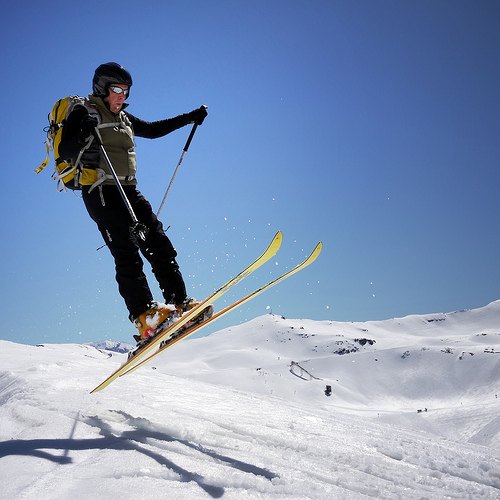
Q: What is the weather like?
A: It is clear.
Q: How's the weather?
A: It is clear.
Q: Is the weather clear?
A: Yes, it is clear.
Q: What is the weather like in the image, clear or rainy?
A: It is clear.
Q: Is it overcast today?
A: No, it is clear.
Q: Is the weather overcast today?
A: No, it is clear.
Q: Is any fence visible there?
A: No, there are no fences.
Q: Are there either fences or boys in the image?
A: No, there are no fences or boys.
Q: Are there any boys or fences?
A: No, there are no fences or boys.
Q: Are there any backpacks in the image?
A: Yes, there is a backpack.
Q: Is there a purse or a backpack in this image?
A: Yes, there is a backpack.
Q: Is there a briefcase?
A: No, there are no briefcases.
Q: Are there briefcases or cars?
A: No, there are no briefcases or cars.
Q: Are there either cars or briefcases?
A: No, there are no briefcases or cars.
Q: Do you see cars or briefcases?
A: No, there are no briefcases or cars.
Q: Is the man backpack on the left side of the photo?
A: Yes, the backpack is on the left of the image.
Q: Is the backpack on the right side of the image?
A: No, the backpack is on the left of the image.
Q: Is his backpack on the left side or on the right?
A: The backpack is on the left of the image.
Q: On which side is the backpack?
A: The backpack is on the left of the image.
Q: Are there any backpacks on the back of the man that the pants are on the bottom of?
A: Yes, there is a backpack on the back of the man.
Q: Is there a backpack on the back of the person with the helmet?
A: Yes, there is a backpack on the back of the man.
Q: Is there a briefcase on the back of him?
A: No, there is a backpack on the back of the man.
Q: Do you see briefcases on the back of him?
A: No, there is a backpack on the back of the man.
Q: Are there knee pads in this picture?
A: No, there are no knee pads.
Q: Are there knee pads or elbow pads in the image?
A: No, there are no knee pads or elbow pads.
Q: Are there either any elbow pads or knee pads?
A: No, there are no knee pads or elbow pads.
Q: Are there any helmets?
A: Yes, there is a helmet.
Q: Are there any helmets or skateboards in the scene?
A: Yes, there is a helmet.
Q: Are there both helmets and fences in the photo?
A: No, there is a helmet but no fences.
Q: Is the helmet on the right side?
A: No, the helmet is on the left of the image.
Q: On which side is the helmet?
A: The helmet is on the left of the image.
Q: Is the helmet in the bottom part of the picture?
A: No, the helmet is in the top of the image.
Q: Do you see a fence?
A: No, there are no fences.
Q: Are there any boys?
A: No, there are no boys.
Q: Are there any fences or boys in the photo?
A: No, there are no boys or fences.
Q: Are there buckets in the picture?
A: No, there are no buckets.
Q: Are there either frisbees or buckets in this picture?
A: No, there are no buckets or frisbees.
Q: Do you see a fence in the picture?
A: No, there are no fences.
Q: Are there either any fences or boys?
A: No, there are no boys or fences.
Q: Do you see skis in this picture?
A: Yes, there are skis.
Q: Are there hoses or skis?
A: Yes, there are skis.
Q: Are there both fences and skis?
A: No, there are skis but no fences.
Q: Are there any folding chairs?
A: No, there are no folding chairs.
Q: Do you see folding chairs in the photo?
A: No, there are no folding chairs.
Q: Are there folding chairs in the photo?
A: No, there are no folding chairs.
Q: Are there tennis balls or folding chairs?
A: No, there are no folding chairs or tennis balls.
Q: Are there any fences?
A: No, there are no fences.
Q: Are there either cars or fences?
A: No, there are no fences or cars.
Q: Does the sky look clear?
A: Yes, the sky is clear.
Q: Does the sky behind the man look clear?
A: Yes, the sky is clear.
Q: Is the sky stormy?
A: No, the sky is clear.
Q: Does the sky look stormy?
A: No, the sky is clear.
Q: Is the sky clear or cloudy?
A: The sky is clear.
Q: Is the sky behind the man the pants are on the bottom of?
A: Yes, the sky is behind the man.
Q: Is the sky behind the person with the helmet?
A: Yes, the sky is behind the man.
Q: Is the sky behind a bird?
A: No, the sky is behind the man.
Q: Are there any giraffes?
A: No, there are no giraffes.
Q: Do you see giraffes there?
A: No, there are no giraffes.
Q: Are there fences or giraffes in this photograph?
A: No, there are no giraffes or fences.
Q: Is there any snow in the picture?
A: Yes, there is snow.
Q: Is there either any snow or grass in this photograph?
A: Yes, there is snow.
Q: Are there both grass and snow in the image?
A: No, there is snow but no grass.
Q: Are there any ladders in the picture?
A: No, there are no ladders.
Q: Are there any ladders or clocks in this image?
A: No, there are no ladders or clocks.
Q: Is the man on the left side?
A: Yes, the man is on the left of the image.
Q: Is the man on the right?
A: No, the man is on the left of the image.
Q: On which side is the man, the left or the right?
A: The man is on the left of the image.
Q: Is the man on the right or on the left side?
A: The man is on the left of the image.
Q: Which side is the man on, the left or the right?
A: The man is on the left of the image.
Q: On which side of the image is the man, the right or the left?
A: The man is on the left of the image.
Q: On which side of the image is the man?
A: The man is on the left of the image.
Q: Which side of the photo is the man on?
A: The man is on the left of the image.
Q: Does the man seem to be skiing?
A: Yes, the man is skiing.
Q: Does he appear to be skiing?
A: Yes, the man is skiing.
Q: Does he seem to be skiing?
A: Yes, the man is skiing.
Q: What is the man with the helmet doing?
A: The man is skiing.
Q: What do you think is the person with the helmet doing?
A: The man is skiing.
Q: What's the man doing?
A: The man is skiing.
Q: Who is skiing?
A: The man is skiing.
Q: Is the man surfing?
A: No, the man is skiing.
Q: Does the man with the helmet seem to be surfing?
A: No, the man is skiing.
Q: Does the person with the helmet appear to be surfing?
A: No, the man is skiing.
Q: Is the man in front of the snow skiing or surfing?
A: The man is skiing.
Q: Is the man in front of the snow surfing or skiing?
A: The man is skiing.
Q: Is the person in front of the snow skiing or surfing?
A: The man is skiing.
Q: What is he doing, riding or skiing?
A: The man is skiing.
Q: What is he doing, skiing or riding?
A: The man is skiing.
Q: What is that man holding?
A: The man is holding the pole.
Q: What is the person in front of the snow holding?
A: The man is holding the pole.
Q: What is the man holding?
A: The man is holding the pole.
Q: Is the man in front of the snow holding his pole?
A: Yes, the man is holding the pole.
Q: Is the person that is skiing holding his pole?
A: Yes, the man is holding the pole.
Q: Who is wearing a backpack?
A: The man is wearing a backpack.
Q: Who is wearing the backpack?
A: The man is wearing a backpack.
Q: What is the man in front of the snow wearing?
A: The man is wearing a backpack.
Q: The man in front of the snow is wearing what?
A: The man is wearing a backpack.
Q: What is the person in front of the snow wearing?
A: The man is wearing a backpack.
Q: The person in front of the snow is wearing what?
A: The man is wearing a backpack.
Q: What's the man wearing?
A: The man is wearing a backpack.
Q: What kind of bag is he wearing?
A: The man is wearing a backpack.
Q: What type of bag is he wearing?
A: The man is wearing a backpack.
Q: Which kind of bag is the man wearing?
A: The man is wearing a backpack.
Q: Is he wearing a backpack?
A: Yes, the man is wearing a backpack.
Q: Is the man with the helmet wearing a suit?
A: No, the man is wearing a backpack.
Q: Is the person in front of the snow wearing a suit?
A: No, the man is wearing a backpack.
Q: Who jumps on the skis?
A: The man jumps on the skis.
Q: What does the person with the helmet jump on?
A: The man jumps on the skis.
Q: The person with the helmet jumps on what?
A: The man jumps on the skis.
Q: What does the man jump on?
A: The man jumps on the skis.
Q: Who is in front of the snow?
A: The man is in front of the snow.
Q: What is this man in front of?
A: The man is in front of the snow.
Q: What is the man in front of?
A: The man is in front of the snow.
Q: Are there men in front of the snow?
A: Yes, there is a man in front of the snow.